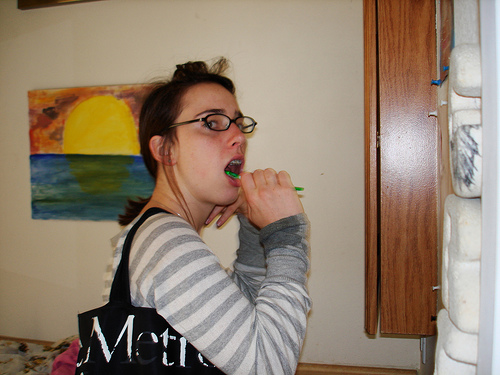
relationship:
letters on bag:
[75, 316, 212, 368] [76, 207, 223, 371]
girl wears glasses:
[71, 56, 313, 373] [165, 111, 257, 134]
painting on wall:
[25, 80, 166, 224] [10, 11, 422, 352]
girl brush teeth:
[76, 58, 312, 374] [223, 161, 244, 178]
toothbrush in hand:
[223, 169, 303, 193] [235, 167, 306, 232]